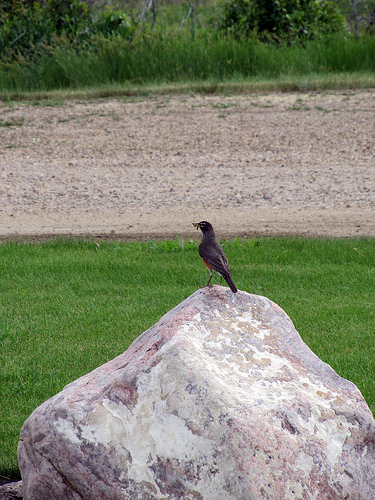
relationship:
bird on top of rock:
[190, 219, 238, 294] [14, 284, 374, 500]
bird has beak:
[190, 219, 238, 294] [190, 221, 200, 229]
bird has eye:
[190, 219, 238, 294] [199, 222, 206, 227]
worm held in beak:
[193, 222, 200, 231] [190, 221, 200, 229]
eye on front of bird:
[199, 222, 206, 227] [190, 219, 238, 294]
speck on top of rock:
[51, 415, 83, 447] [14, 284, 374, 500]